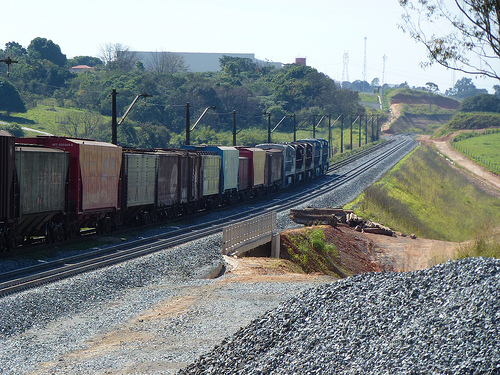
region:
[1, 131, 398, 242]
freight cars on a railroad track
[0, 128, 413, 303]
empty railroad track beside occupied track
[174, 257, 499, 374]
gravel pile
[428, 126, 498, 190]
dirt track alongside fenced field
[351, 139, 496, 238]
grassy slope below railroad track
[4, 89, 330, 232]
poles and power line behind train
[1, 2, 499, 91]
hazy sky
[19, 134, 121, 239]
orange-red freight car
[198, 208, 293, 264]
culvert under railroad tracks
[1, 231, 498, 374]
flat area between gravel pile and railroad track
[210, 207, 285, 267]
bridge over gap in hill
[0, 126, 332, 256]
long train moving along train tracks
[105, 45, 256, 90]
light gray and white building on hillside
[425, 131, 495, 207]
narrow dirt road near train tracks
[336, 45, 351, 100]
metal power line tower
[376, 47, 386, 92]
metal tower on hillside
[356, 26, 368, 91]
metal tower on hillside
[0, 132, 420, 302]
long narrow metal train tracks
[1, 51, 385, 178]
row of wires along train tracks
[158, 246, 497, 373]
large pile of gravel on hill near train tracks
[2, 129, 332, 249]
the train on the track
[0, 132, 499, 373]
the rocks around and near the train tracks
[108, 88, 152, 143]
the light pole next to the train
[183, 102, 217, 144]
the light pole next to the train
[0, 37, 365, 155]
the green trees near the train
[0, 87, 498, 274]
the green grass near the train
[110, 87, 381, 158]
the row of light poles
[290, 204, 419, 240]
the wood logs near the train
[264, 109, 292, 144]
the light pole near the train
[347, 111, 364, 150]
v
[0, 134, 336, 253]
the cars of a train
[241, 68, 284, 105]
the leaves on a tree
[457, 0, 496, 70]
the branches of a tree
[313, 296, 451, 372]
a pile of gravel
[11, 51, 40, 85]
the leaves of a tree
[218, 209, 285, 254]
the railing of a bridge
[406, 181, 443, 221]
the grass on the side of a hill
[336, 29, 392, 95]
three phone towers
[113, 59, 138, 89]
the leaves of tree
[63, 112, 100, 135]
the branches of a tree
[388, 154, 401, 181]
part of a hill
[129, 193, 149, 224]
part of a train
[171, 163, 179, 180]
edge of a train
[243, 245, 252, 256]
part of a bridge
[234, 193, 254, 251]
side of a bridge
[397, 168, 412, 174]
part of a slope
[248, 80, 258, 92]
part of a forest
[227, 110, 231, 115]
part of a fence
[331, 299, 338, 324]
edge of a rock